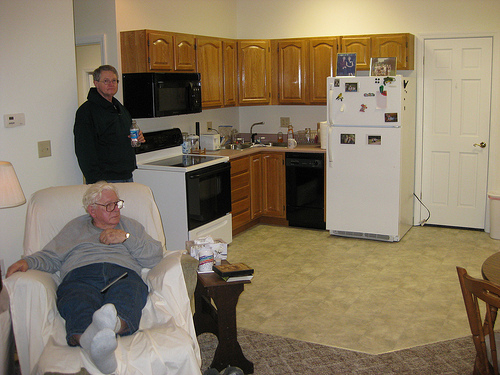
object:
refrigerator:
[323, 70, 417, 244]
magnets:
[384, 112, 400, 123]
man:
[2, 178, 165, 372]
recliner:
[0, 178, 204, 375]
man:
[70, 63, 146, 185]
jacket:
[71, 86, 138, 186]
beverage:
[129, 119, 141, 149]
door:
[417, 29, 495, 232]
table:
[191, 264, 255, 375]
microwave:
[122, 72, 204, 119]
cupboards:
[270, 36, 413, 108]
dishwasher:
[284, 151, 325, 231]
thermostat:
[2, 111, 26, 128]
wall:
[2, 1, 84, 252]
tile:
[303, 255, 446, 305]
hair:
[81, 179, 119, 217]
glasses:
[92, 199, 124, 213]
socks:
[76, 302, 121, 372]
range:
[131, 126, 233, 267]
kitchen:
[116, 2, 499, 253]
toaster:
[199, 132, 221, 151]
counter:
[260, 142, 326, 152]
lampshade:
[0, 158, 28, 210]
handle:
[327, 128, 333, 168]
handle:
[328, 88, 334, 125]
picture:
[336, 53, 356, 76]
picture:
[370, 56, 396, 76]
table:
[479, 246, 500, 295]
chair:
[452, 264, 498, 374]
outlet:
[206, 121, 212, 132]